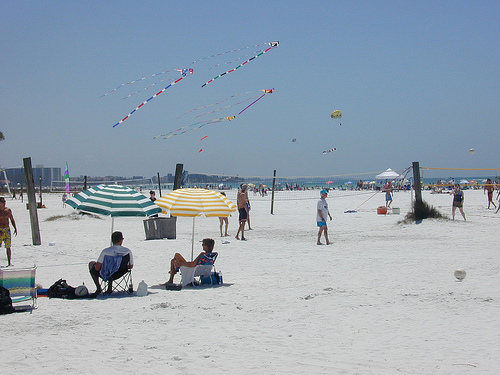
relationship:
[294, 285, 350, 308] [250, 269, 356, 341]
tracks in sand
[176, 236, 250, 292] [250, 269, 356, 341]
chair on sand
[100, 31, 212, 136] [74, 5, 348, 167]
skit in sky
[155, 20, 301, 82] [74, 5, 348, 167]
kite in air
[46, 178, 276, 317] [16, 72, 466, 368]
people on beach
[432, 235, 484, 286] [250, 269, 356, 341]
ball on sand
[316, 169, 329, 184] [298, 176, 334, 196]
water has edge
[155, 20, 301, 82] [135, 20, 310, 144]
kite in air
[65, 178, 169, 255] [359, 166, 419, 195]
green and white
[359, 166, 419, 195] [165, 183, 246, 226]
white and yellow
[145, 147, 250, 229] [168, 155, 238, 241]
umbrella has stripes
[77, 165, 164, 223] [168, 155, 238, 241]
umbrella has stripes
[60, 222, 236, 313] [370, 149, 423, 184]
couple beneath umbrella